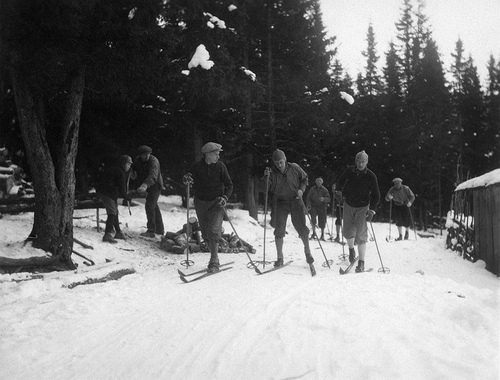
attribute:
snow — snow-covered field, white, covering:
[1, 194, 499, 380]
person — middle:
[256, 148, 314, 268]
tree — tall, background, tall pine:
[390, 0, 416, 105]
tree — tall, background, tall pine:
[409, 1, 434, 91]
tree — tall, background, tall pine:
[248, 0, 294, 168]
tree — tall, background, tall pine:
[305, 2, 337, 104]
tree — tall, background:
[220, 32, 267, 224]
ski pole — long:
[256, 167, 273, 270]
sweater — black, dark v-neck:
[184, 156, 234, 203]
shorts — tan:
[341, 202, 369, 246]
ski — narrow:
[256, 261, 291, 275]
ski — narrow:
[308, 263, 316, 277]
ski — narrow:
[339, 255, 359, 275]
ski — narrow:
[354, 267, 372, 273]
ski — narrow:
[179, 266, 234, 284]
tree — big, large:
[0, 0, 188, 273]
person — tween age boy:
[97, 154, 133, 243]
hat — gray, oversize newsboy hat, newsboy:
[200, 141, 223, 155]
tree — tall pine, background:
[140, 1, 257, 165]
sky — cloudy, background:
[272, 0, 499, 100]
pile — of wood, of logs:
[159, 216, 257, 255]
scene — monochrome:
[1, 1, 500, 378]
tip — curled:
[179, 274, 190, 282]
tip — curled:
[255, 268, 264, 274]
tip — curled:
[340, 268, 348, 276]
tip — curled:
[177, 269, 188, 276]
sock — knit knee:
[347, 237, 355, 248]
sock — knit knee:
[358, 243, 366, 263]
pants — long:
[145, 182, 165, 234]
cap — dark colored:
[135, 145, 153, 156]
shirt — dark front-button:
[201, 159, 215, 176]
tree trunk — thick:
[7, 50, 86, 256]